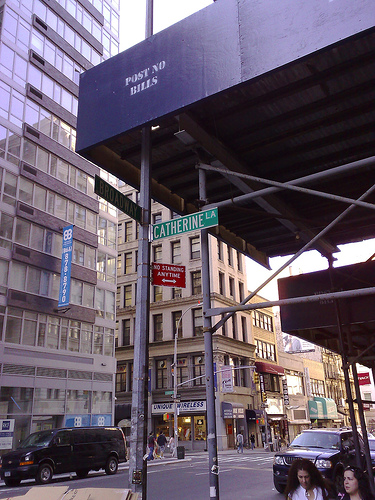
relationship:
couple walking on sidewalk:
[340, 466, 371, 500] [279, 195, 374, 500]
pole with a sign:
[129, 129, 153, 500] [151, 262, 188, 290]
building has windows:
[2, 1, 116, 428] [91, 324, 116, 355]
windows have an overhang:
[152, 312, 164, 341] [213, 336, 258, 359]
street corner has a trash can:
[144, 397, 210, 499] [176, 444, 186, 462]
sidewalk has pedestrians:
[145, 447, 192, 468] [146, 429, 171, 462]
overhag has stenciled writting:
[76, 5, 374, 256] [126, 58, 167, 96]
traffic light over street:
[214, 364, 262, 389] [141, 451, 275, 499]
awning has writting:
[76, 5, 374, 256] [126, 58, 167, 96]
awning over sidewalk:
[245, 405, 259, 423] [218, 438, 276, 454]